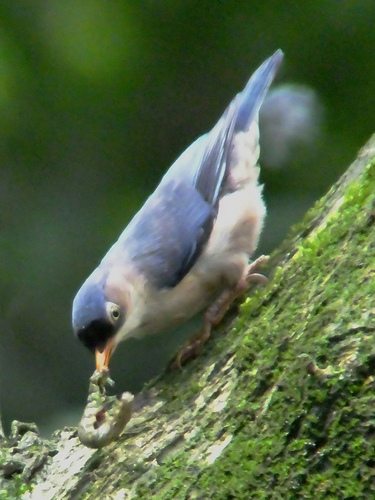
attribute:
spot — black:
[78, 314, 118, 344]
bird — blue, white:
[14, 67, 316, 342]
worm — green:
[65, 369, 189, 460]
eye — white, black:
[101, 301, 127, 327]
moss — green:
[203, 333, 369, 495]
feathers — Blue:
[167, 140, 223, 216]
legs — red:
[169, 250, 277, 370]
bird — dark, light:
[67, 46, 285, 380]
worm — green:
[75, 368, 134, 448]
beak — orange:
[93, 342, 114, 373]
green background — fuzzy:
[2, 2, 372, 431]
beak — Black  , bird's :
[89, 342, 119, 373]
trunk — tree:
[210, 234, 357, 466]